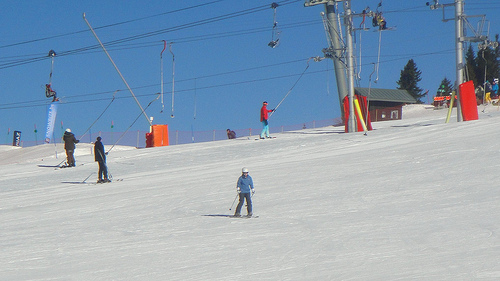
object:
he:
[258, 101, 275, 140]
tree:
[396, 58, 429, 105]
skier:
[371, 10, 388, 31]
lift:
[315, 25, 337, 45]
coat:
[260, 105, 273, 121]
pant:
[259, 120, 270, 137]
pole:
[450, 0, 467, 124]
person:
[230, 167, 261, 218]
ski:
[229, 213, 259, 219]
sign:
[485, 79, 500, 104]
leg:
[234, 194, 245, 217]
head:
[242, 168, 248, 177]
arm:
[236, 177, 242, 193]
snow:
[199, 219, 277, 257]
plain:
[99, 183, 183, 265]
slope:
[134, 142, 198, 274]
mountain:
[349, 155, 436, 246]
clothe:
[94, 142, 111, 181]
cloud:
[187, 41, 231, 80]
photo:
[0, 0, 500, 281]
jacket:
[236, 174, 254, 194]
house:
[344, 89, 411, 126]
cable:
[0, 35, 143, 69]